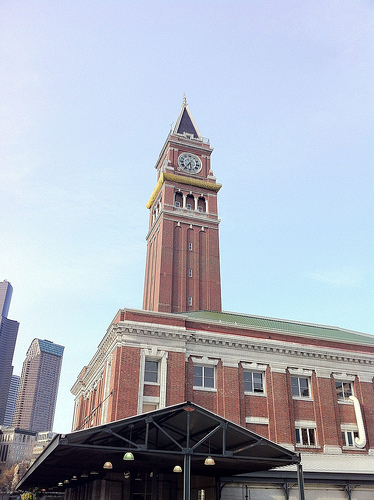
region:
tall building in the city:
[11, 334, 69, 457]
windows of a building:
[189, 351, 221, 391]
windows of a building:
[139, 354, 164, 383]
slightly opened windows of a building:
[240, 364, 267, 396]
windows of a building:
[284, 371, 311, 400]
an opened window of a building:
[291, 416, 320, 451]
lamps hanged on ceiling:
[200, 431, 217, 467]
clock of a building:
[178, 151, 204, 178]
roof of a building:
[168, 90, 205, 139]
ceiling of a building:
[8, 398, 308, 479]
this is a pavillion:
[83, 400, 152, 489]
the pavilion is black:
[123, 424, 211, 496]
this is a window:
[193, 328, 235, 467]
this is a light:
[92, 447, 155, 493]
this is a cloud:
[16, 263, 60, 316]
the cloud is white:
[18, 254, 57, 317]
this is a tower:
[134, 268, 270, 367]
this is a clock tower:
[94, 261, 243, 357]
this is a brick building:
[138, 343, 191, 411]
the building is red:
[95, 380, 182, 406]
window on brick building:
[143, 359, 156, 382]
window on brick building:
[195, 366, 203, 387]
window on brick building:
[202, 366, 213, 389]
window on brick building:
[242, 368, 253, 393]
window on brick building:
[251, 370, 264, 392]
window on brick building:
[288, 374, 298, 395]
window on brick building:
[295, 374, 306, 393]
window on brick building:
[331, 376, 338, 392]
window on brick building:
[340, 379, 348, 398]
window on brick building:
[293, 427, 300, 446]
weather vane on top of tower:
[177, 90, 190, 108]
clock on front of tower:
[176, 148, 204, 175]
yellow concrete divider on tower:
[140, 170, 223, 210]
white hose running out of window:
[347, 393, 371, 451]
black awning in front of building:
[11, 393, 314, 498]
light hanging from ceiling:
[203, 435, 215, 467]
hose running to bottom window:
[332, 388, 372, 449]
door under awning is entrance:
[127, 470, 158, 498]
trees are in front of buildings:
[1, 458, 26, 488]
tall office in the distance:
[12, 333, 66, 432]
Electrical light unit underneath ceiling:
[121, 449, 138, 463]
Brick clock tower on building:
[142, 79, 224, 307]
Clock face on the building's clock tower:
[175, 148, 211, 173]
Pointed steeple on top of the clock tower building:
[166, 88, 219, 137]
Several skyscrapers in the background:
[0, 270, 78, 435]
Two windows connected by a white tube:
[331, 369, 369, 454]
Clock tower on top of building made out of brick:
[130, 84, 235, 309]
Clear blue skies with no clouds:
[52, 15, 345, 82]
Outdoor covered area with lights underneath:
[13, 399, 305, 497]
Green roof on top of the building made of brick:
[175, 298, 373, 356]